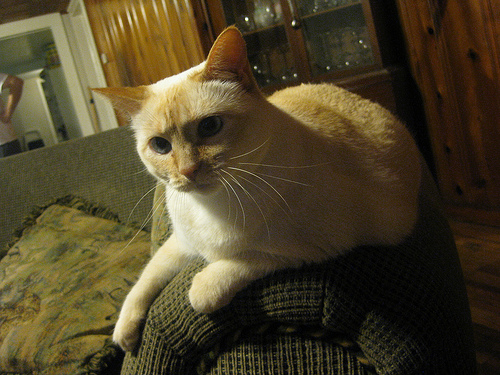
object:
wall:
[88, 0, 492, 206]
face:
[137, 104, 235, 196]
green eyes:
[192, 114, 223, 146]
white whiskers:
[215, 176, 233, 214]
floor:
[457, 187, 488, 262]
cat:
[112, 22, 427, 356]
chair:
[0, 97, 478, 375]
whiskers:
[121, 184, 171, 252]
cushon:
[0, 194, 161, 373]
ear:
[86, 86, 154, 119]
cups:
[318, 20, 373, 71]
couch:
[0, 126, 479, 374]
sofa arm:
[119, 175, 466, 375]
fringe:
[3, 189, 148, 259]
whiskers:
[96, 135, 336, 255]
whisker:
[229, 165, 296, 215]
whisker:
[228, 134, 272, 158]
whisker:
[220, 175, 247, 232]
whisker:
[221, 167, 251, 200]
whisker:
[238, 161, 320, 189]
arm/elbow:
[0, 74, 29, 121]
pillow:
[2, 190, 177, 374]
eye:
[146, 135, 173, 155]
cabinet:
[82, 2, 438, 202]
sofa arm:
[141, 189, 473, 374]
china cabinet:
[188, 1, 399, 107]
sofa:
[9, 61, 476, 373]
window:
[301, 3, 379, 78]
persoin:
[1, 67, 29, 160]